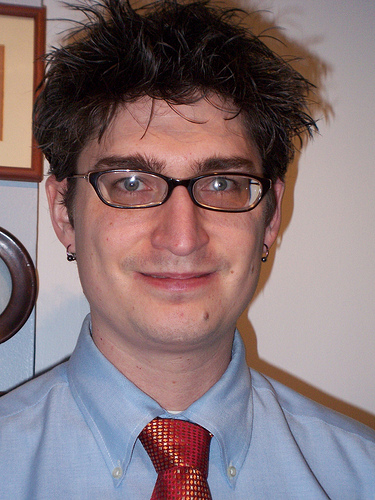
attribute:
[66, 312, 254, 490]
collar — blue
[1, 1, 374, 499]
man — spectacle, smiling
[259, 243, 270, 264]
part — black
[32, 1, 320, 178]
hair — brown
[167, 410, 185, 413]
shirt — white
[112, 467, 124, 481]
button — small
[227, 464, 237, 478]
button — small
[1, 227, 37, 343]
circle — round, shiny, black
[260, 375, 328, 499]
crease — long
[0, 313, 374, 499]
shirt — blue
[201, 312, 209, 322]
mole — black, small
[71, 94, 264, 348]
face — shaved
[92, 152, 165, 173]
brow — bushy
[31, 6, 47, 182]
edge — brown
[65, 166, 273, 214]
glasses — black, plastic, metal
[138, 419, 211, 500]
tie — red, knotted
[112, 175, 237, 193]
eyes — blue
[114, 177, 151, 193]
eye — blue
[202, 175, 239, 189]
eye — blue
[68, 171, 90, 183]
glasses — metal